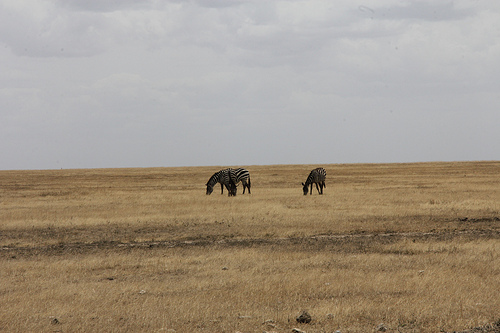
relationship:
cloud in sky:
[0, 0, 500, 171] [0, 0, 500, 171]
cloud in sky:
[230, 10, 323, 63] [16, 19, 484, 136]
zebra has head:
[205, 168, 250, 197] [203, 172, 217, 197]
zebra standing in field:
[205, 168, 250, 197] [7, 161, 488, 327]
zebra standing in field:
[301, 167, 326, 195] [7, 161, 488, 327]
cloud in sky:
[0, 0, 500, 171] [71, 27, 167, 97]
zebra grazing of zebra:
[205, 168, 250, 197] [298, 163, 328, 197]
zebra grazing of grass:
[205, 168, 250, 197] [174, 192, 208, 212]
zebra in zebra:
[301, 167, 326, 195] [221, 167, 239, 197]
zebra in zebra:
[301, 167, 326, 195] [203, 166, 253, 196]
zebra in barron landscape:
[301, 167, 326, 195] [34, 196, 394, 329]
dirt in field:
[9, 220, 498, 262] [7, 161, 488, 327]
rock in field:
[296, 310, 311, 323] [7, 161, 488, 327]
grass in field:
[1, 159, 496, 327] [7, 161, 488, 327]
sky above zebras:
[0, 0, 500, 171] [193, 140, 334, 220]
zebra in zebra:
[205, 168, 250, 197] [301, 167, 326, 195]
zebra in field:
[203, 166, 253, 196] [7, 161, 488, 327]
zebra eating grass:
[285, 160, 347, 215] [246, 192, 338, 225]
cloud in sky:
[0, 0, 500, 171] [8, 55, 495, 158]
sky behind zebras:
[393, 29, 498, 101] [188, 158, 354, 215]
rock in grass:
[296, 310, 311, 323] [1, 159, 496, 327]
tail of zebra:
[321, 171, 326, 186] [300, 165, 327, 195]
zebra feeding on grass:
[205, 168, 250, 197] [66, 256, 168, 314]